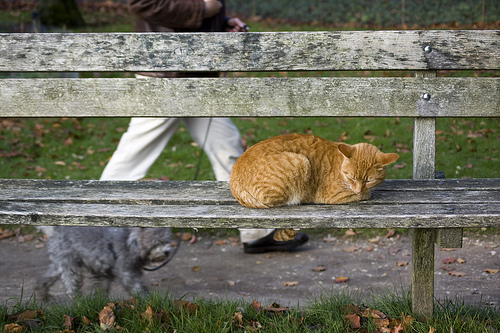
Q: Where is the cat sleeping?
A: On a bench.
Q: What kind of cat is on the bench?
A: An orange tabby.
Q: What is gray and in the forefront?
A: The wooden bench.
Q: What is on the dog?
A: A leash.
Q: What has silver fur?
A: The dog.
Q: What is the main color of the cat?
A: Orange.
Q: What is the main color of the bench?
A: Brown.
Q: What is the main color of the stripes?
A: Orange.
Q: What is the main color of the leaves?
A: Brown.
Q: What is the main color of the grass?
A: Green.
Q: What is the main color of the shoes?
A: Black.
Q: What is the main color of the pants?
A: White.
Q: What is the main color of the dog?
A: Gray.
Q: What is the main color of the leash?
A: Black.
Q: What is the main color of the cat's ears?
A: Orange.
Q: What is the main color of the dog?
A: Gray.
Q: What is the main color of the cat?
A: Orange.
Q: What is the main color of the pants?
A: White.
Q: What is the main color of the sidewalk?
A: Gray.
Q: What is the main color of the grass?
A: Green.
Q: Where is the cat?
A: On a bench.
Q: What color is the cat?
A: Orange.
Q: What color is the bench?
A: Gray.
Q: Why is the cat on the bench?
A: He is sleeping.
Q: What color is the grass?
A: Green.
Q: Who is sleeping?
A: The cat.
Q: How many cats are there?
A: One.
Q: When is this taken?
A: During the daytime.